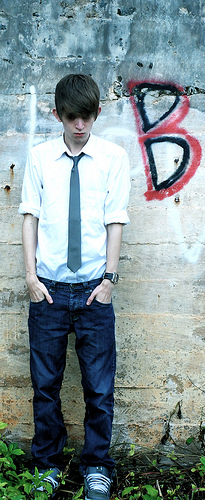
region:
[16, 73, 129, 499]
young man standing against wall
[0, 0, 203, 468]
a stone wall behind the young man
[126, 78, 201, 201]
graffiti on the wall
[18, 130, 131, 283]
a white shirt on the young man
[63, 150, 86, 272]
a thin tie on the young man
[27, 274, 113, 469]
blue jeans on the young man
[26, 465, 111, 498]
skater shoes on the young man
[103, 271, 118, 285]
large watch on the man's wrist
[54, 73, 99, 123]
hair covering man's eyes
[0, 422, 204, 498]
plants on the ground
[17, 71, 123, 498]
boy with brown hair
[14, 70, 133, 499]
boy with short hair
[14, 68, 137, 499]
boy wearing white shirt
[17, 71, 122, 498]
boy wearing grey tie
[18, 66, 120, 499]
boy wearing dark blue denim jeans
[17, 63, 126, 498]
boy wearing tennis shoes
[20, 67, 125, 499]
boy with hands in both pockets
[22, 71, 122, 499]
boy looking down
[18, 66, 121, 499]
boy wearing watch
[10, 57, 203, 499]
graffiti near boy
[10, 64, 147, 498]
This is a boy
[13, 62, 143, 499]
This is a school boy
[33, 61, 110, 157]
Head of a boy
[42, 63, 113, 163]
Head of a school boy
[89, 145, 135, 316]
Hand of a boy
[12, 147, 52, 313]
Hand of a boy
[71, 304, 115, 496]
Leg of a boy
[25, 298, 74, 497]
Leg of a boy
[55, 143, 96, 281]
This is a tie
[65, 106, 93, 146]
Face of a boy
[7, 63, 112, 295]
Boy standing against wall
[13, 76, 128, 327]
Boys standing with hands in pockets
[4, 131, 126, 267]
Dress shirt and tie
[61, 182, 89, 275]
Tie is gray in color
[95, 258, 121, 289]
Wristwatch on left arm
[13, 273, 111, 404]
Blue denim pants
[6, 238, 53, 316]
Right hand in pocket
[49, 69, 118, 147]
Boy has brown hair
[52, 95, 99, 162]
Boy has long bangs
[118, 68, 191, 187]
Graffitti on wall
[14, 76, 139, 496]
The boy is standing.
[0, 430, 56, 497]
Green leaves on a small plant.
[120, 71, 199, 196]
The letter B is sprayed painted on the wall.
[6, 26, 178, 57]
The wall is grey.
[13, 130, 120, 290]
The boy is wearing a white shirt.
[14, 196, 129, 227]
The sleeves are rolled up on the shirt.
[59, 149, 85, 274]
The boy is wearing a tie.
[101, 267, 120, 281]
The boy is wearing a watch.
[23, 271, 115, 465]
The boy is wearing jeans.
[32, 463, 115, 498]
The boy is wearing white laced shoes.